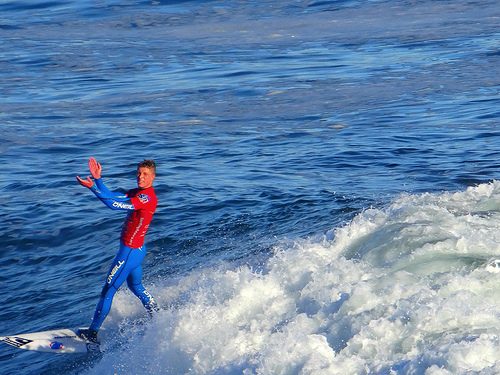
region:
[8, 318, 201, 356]
surfboard used by a man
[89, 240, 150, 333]
man wearing blue color pant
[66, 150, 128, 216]
man lifting his hand up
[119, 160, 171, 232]
man focusing on the camera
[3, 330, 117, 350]
white color surf board in the sea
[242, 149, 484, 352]
big waves in the sea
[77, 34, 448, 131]
blue color sky water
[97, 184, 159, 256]
man wearing full hand t-shirt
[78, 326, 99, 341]
man wearing black color shoe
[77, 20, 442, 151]
small waves in the water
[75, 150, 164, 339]
man wearing red shirt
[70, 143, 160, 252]
red shirt with blue leaves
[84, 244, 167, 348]
blue pants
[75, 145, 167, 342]
man wearing pair of blue pants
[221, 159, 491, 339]
white waves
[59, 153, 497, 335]
white ocean waves behind man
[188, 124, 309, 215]
clear blue ocean water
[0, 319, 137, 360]
white surfboard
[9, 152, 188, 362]
man standing on white surfboard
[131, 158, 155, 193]
man with short brown hair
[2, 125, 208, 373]
person surfing in ocean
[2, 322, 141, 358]
white surfboard in ocean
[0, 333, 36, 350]
black and white sticker on surfboard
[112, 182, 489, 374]
white waves in ocean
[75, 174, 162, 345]
red and blue wetsuit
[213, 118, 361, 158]
ripples in body of water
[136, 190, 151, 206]
label on shoulder of red portion of wet suit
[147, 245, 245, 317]
white water splash residue in air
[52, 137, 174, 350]
man standing on surfboard clapping hands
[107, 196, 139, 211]
brand name in white lettering on sleeve of wetsuit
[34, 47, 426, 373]
a man surfing on the water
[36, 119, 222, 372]
a man surfing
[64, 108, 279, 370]
a man that is surfing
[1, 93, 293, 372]
a man on a surfboard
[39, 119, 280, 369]
a man standing on a surfboard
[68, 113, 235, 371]
a man in a wetsuit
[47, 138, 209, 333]
a man in a red and blue wetsuit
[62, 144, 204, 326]
a surfer in a wetsuit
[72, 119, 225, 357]
a surfer in a red and blue wetsuit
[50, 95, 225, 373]
a surfer on the water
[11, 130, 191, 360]
a man is surfing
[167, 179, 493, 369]
waves are behind the man on his surfboard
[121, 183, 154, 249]
the man is wearing a red shirt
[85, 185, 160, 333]
the mans we suit is blue in color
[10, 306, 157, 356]
a portion of the mans surfboard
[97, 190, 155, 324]
the lettering on the mans wet suit is white in color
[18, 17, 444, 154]
this portion of the area is made up of water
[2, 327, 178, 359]
the mans surfboard is white in color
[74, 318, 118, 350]
the mans shoe is black in color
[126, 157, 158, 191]
Here is the mans face